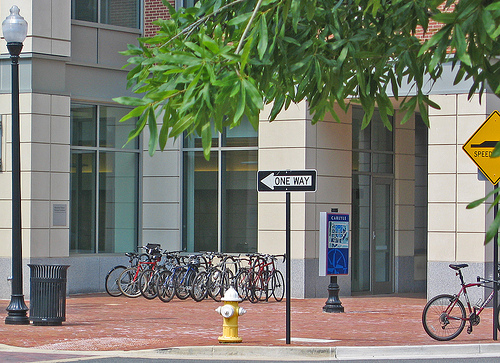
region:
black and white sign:
[245, 158, 352, 207]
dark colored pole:
[275, 191, 305, 356]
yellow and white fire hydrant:
[203, 274, 258, 353]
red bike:
[404, 246, 499, 346]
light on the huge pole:
[4, 1, 36, 49]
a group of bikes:
[82, 220, 306, 312]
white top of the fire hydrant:
[221, 283, 247, 304]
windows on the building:
[168, 98, 270, 260]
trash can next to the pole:
[16, 257, 84, 333]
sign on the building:
[46, 191, 76, 233]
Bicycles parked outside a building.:
[43, 51, 316, 323]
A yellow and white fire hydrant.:
[203, 285, 248, 342]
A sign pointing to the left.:
[252, 161, 324, 193]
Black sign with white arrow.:
[255, 161, 315, 195]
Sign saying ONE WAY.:
[254, 165, 318, 192]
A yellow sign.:
[463, 105, 498, 178]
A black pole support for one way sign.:
[283, 193, 298, 343]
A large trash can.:
[21, 262, 83, 334]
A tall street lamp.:
[2, 5, 31, 323]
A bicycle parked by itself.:
[413, 250, 498, 342]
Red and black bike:
[409, 255, 499, 340]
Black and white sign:
[245, 161, 333, 208]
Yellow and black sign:
[457, 104, 498, 191]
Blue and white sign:
[309, 199, 357, 302]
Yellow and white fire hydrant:
[207, 278, 250, 353]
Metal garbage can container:
[13, 251, 88, 343]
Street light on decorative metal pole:
[0, 11, 37, 340]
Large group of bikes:
[95, 236, 300, 310]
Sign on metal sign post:
[235, 159, 334, 355]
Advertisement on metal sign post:
[315, 199, 352, 325]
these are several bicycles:
[119, 250, 274, 292]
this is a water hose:
[216, 285, 243, 341]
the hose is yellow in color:
[223, 320, 237, 340]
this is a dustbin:
[28, 261, 68, 321]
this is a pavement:
[87, 295, 143, 342]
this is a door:
[354, 178, 396, 283]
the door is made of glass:
[371, 197, 393, 269]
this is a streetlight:
[6, 4, 26, 319]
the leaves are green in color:
[178, 25, 367, 102]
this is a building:
[32, 1, 125, 261]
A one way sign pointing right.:
[255, 167, 320, 345]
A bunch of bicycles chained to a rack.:
[104, 240, 287, 302]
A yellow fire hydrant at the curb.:
[215, 285, 247, 344]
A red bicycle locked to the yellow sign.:
[421, 257, 499, 343]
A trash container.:
[24, 261, 74, 328]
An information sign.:
[315, 205, 355, 314]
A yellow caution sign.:
[460, 110, 499, 342]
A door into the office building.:
[350, 170, 398, 299]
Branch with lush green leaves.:
[111, 0, 498, 157]